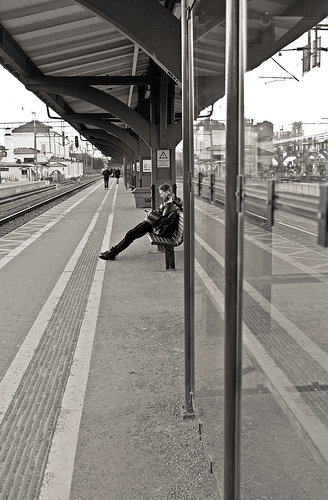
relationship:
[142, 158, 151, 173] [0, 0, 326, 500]
white sign posted on railway station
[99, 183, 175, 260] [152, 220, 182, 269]
man sitting on a bench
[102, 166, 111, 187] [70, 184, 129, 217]
man walking on platform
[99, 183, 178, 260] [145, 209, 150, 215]
man texting on phone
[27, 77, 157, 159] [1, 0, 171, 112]
metal arches attached to roofing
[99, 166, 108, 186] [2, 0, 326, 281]
man standing in train station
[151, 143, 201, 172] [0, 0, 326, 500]
sign posted in railway station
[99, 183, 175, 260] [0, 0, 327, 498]
man seated at railway station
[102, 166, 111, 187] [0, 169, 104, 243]
man walking alongside tracks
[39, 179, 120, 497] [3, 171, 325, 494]
line painted on ground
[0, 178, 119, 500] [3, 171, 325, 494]
line painted on ground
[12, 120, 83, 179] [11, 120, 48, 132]
building with roof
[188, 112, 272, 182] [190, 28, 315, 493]
reflection in glass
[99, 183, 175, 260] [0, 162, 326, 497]
man on platform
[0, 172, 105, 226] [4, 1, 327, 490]
tracks on station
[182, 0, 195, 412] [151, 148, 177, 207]
pillar on pillar